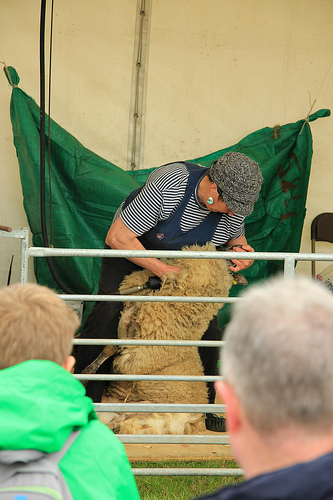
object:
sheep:
[95, 240, 248, 433]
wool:
[89, 397, 209, 435]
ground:
[91, 412, 248, 500]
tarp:
[2, 65, 332, 373]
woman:
[72, 149, 264, 432]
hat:
[205, 151, 267, 219]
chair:
[310, 210, 333, 281]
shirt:
[110, 160, 250, 248]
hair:
[213, 267, 332, 438]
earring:
[207, 196, 214, 205]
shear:
[117, 275, 164, 295]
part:
[309, 210, 332, 246]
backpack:
[0, 412, 95, 500]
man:
[193, 269, 333, 499]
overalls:
[69, 160, 249, 417]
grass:
[128, 458, 246, 500]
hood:
[0, 357, 98, 455]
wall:
[1, 2, 333, 290]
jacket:
[0, 357, 144, 500]